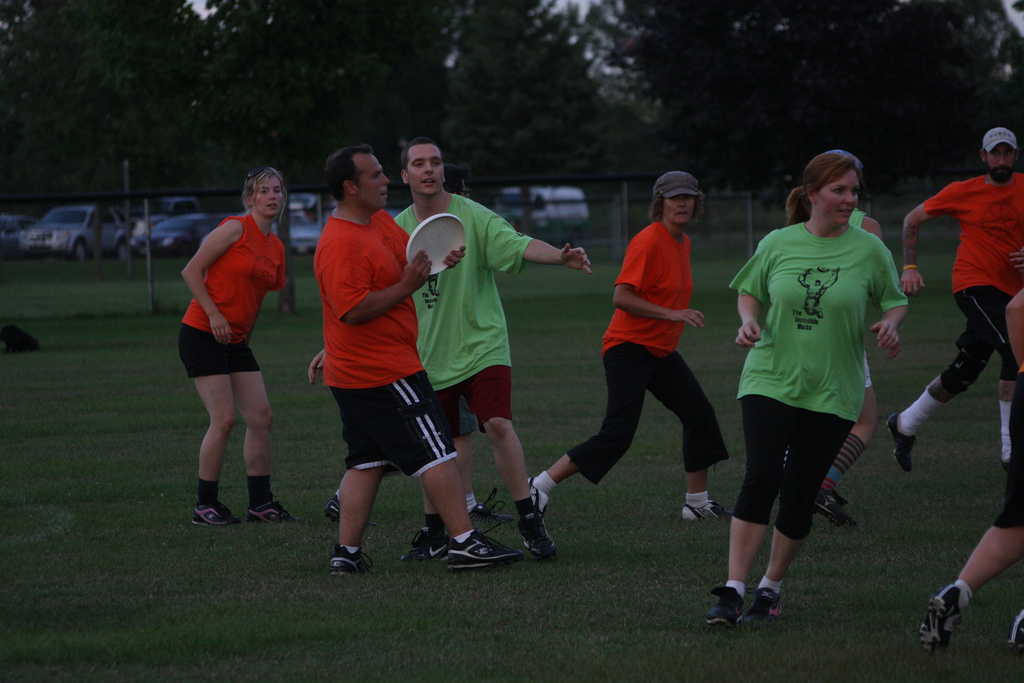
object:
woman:
[528, 171, 734, 523]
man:
[885, 127, 1024, 472]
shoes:
[191, 500, 301, 526]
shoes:
[917, 583, 1023, 661]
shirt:
[183, 213, 286, 344]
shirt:
[602, 221, 693, 358]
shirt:
[314, 209, 424, 388]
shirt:
[726, 223, 906, 424]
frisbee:
[406, 213, 467, 276]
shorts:
[178, 322, 261, 378]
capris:
[733, 394, 856, 541]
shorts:
[329, 370, 457, 478]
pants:
[569, 342, 730, 486]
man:
[314, 145, 522, 574]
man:
[306, 138, 593, 559]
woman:
[710, 152, 907, 629]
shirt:
[394, 194, 533, 392]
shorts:
[432, 365, 512, 439]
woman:
[178, 165, 303, 526]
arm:
[183, 219, 244, 314]